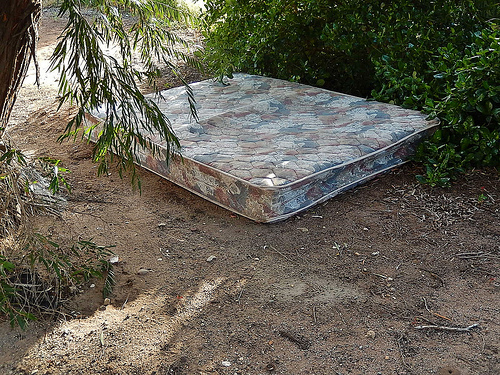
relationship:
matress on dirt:
[77, 66, 449, 219] [194, 205, 423, 334]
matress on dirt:
[77, 66, 449, 219] [132, 185, 433, 286]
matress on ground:
[77, 66, 449, 219] [71, 162, 313, 307]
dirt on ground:
[327, 215, 499, 354] [103, 150, 303, 301]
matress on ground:
[77, 66, 449, 219] [110, 217, 359, 330]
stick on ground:
[413, 322, 480, 335] [0, 7, 499, 373]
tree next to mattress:
[210, 4, 497, 89] [86, 74, 441, 206]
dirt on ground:
[0, 0, 500, 375] [149, 217, 355, 327]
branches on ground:
[23, 245, 89, 305] [112, 210, 378, 338]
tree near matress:
[2, 0, 204, 194] [77, 66, 449, 219]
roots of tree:
[33, 195, 138, 310] [15, 4, 235, 176]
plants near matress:
[398, 13, 486, 90] [77, 66, 449, 219]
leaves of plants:
[433, 40, 485, 105] [207, 3, 499, 154]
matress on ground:
[72, 29, 474, 271] [0, 7, 499, 373]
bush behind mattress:
[191, 11, 498, 183] [77, 52, 455, 231]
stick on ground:
[392, 321, 412, 369] [0, 7, 499, 373]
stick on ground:
[454, 243, 484, 263] [0, 7, 499, 373]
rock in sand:
[131, 265, 154, 277] [0, 8, 499, 373]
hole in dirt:
[5, 261, 70, 331] [14, 180, 499, 373]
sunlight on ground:
[42, 30, 194, 85] [100, 201, 430, 313]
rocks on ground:
[171, 206, 263, 288] [0, 7, 499, 373]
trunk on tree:
[1, 0, 41, 138] [2, 2, 201, 294]